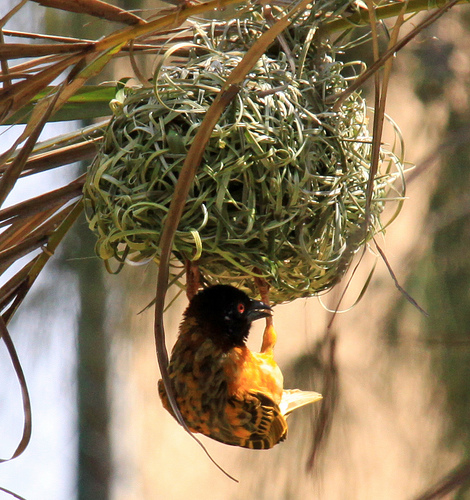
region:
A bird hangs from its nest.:
[143, 245, 354, 465]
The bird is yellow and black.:
[149, 280, 343, 460]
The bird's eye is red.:
[233, 298, 249, 319]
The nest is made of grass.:
[79, 30, 397, 317]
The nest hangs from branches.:
[21, 3, 431, 312]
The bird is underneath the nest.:
[149, 237, 322, 461]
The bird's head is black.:
[159, 276, 285, 356]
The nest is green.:
[75, 14, 406, 308]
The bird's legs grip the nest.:
[170, 243, 299, 355]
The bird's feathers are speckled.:
[160, 323, 311, 456]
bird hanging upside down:
[155, 247, 325, 451]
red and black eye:
[233, 299, 249, 315]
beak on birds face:
[245, 298, 273, 322]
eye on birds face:
[233, 299, 248, 313]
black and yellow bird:
[156, 248, 323, 450]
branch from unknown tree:
[0, 1, 467, 481]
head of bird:
[175, 282, 270, 342]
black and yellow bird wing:
[221, 387, 289, 453]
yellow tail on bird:
[277, 385, 322, 416]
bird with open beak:
[155, 244, 323, 450]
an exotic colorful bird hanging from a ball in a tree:
[65, 227, 339, 491]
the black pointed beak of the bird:
[253, 295, 277, 321]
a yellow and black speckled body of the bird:
[173, 356, 287, 439]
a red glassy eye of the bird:
[233, 303, 247, 313]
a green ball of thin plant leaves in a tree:
[66, 46, 408, 287]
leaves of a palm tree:
[2, 0, 133, 378]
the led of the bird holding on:
[247, 266, 283, 362]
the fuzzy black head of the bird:
[193, 286, 268, 341]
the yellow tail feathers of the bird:
[290, 383, 330, 417]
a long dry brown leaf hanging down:
[149, 266, 204, 473]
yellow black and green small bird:
[159, 280, 322, 447]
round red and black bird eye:
[235, 300, 244, 313]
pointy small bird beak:
[247, 295, 273, 319]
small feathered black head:
[185, 283, 247, 334]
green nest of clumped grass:
[89, 40, 410, 289]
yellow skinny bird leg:
[247, 257, 276, 356]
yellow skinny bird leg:
[175, 252, 207, 298]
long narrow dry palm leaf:
[149, 7, 276, 425]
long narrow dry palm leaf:
[2, 195, 85, 454]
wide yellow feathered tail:
[275, 383, 324, 420]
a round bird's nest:
[102, 53, 369, 268]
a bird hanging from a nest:
[161, 250, 325, 462]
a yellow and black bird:
[152, 272, 331, 441]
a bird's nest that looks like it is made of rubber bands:
[109, 49, 362, 231]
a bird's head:
[148, 270, 307, 361]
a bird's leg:
[257, 314, 291, 358]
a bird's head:
[183, 280, 274, 348]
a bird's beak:
[249, 298, 274, 323]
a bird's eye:
[232, 297, 248, 319]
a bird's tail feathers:
[279, 376, 332, 428]